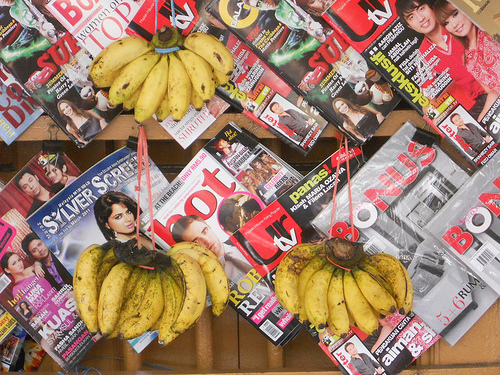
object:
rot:
[72, 233, 227, 338]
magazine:
[423, 133, 499, 346]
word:
[327, 140, 437, 245]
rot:
[291, 256, 306, 271]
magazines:
[27, 162, 154, 333]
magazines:
[217, 0, 381, 137]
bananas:
[106, 51, 163, 106]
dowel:
[193, 306, 213, 373]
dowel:
[266, 341, 286, 373]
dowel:
[121, 338, 142, 370]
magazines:
[133, 122, 306, 340]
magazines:
[293, 135, 429, 374]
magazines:
[0, 148, 107, 368]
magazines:
[423, 149, 498, 301]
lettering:
[148, 212, 189, 250]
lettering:
[179, 185, 222, 220]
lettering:
[196, 165, 237, 197]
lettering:
[362, 175, 405, 215]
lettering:
[385, 150, 422, 185]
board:
[3, 111, 498, 145]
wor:
[147, 164, 246, 249]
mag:
[145, 144, 310, 349]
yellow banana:
[274, 237, 416, 338]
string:
[151, 1, 185, 56]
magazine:
[211, 129, 281, 181]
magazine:
[354, 0, 500, 169]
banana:
[69, 238, 100, 334]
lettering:
[369, 50, 431, 107]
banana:
[272, 240, 325, 322]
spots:
[286, 251, 306, 272]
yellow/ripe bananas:
[177, 46, 215, 103]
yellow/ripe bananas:
[166, 251, 208, 333]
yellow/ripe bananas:
[371, 252, 414, 314]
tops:
[110, 240, 172, 269]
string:
[328, 135, 355, 242]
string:
[135, 125, 156, 250]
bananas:
[72, 237, 107, 328]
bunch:
[271, 237, 412, 339]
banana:
[163, 54, 189, 120]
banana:
[271, 239, 416, 338]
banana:
[364, 250, 416, 317]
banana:
[302, 257, 330, 325]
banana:
[325, 268, 351, 337]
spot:
[337, 299, 346, 306]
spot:
[285, 251, 309, 276]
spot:
[392, 292, 400, 300]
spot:
[285, 290, 291, 297]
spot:
[315, 296, 322, 303]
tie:
[149, 42, 185, 56]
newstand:
[0, 0, 500, 375]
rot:
[121, 79, 135, 90]